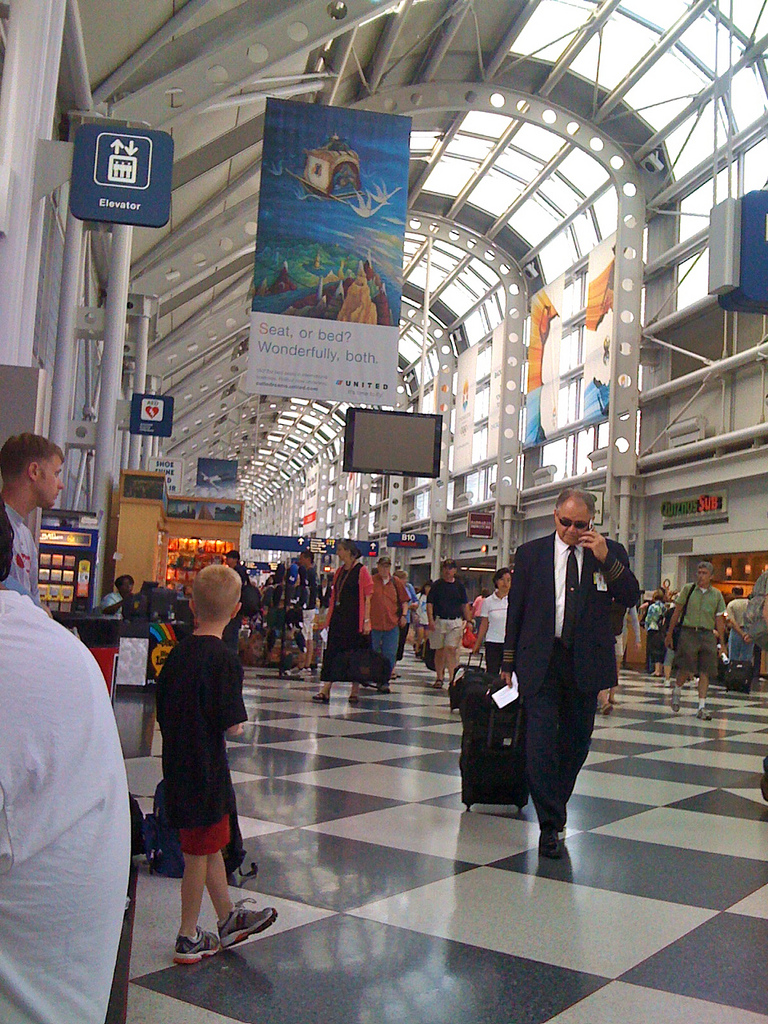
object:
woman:
[312, 536, 384, 716]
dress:
[319, 558, 367, 685]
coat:
[317, 561, 370, 633]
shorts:
[173, 813, 232, 857]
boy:
[152, 570, 274, 972]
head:
[186, 558, 250, 648]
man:
[663, 560, 731, 726]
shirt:
[676, 575, 726, 636]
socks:
[697, 695, 706, 711]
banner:
[245, 96, 413, 414]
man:
[489, 485, 641, 866]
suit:
[506, 531, 644, 837]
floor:
[98, 624, 766, 1021]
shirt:
[157, 633, 250, 824]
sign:
[61, 115, 182, 230]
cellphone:
[580, 518, 596, 545]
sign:
[128, 386, 181, 446]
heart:
[142, 403, 161, 419]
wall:
[640, 494, 768, 547]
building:
[14, 22, 747, 796]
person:
[375, 558, 408, 686]